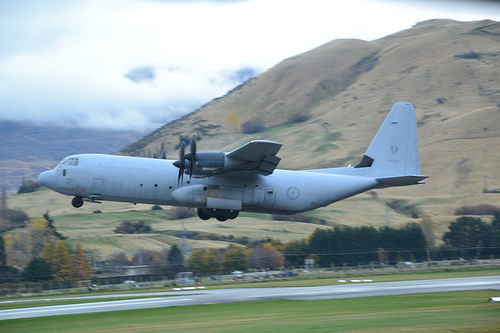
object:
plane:
[37, 100, 428, 242]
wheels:
[196, 204, 216, 221]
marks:
[183, 286, 198, 290]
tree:
[21, 257, 57, 283]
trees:
[247, 239, 285, 269]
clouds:
[0, 0, 500, 132]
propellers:
[171, 139, 187, 186]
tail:
[353, 100, 428, 187]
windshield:
[58, 157, 81, 168]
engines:
[164, 146, 230, 179]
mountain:
[124, 12, 500, 201]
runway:
[0, 275, 500, 321]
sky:
[0, 0, 500, 132]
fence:
[291, 264, 500, 278]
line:
[250, 288, 359, 298]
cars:
[239, 272, 258, 282]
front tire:
[71, 193, 87, 209]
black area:
[354, 156, 378, 169]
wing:
[219, 138, 284, 181]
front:
[37, 149, 91, 198]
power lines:
[251, 245, 500, 260]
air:
[38, 20, 130, 74]